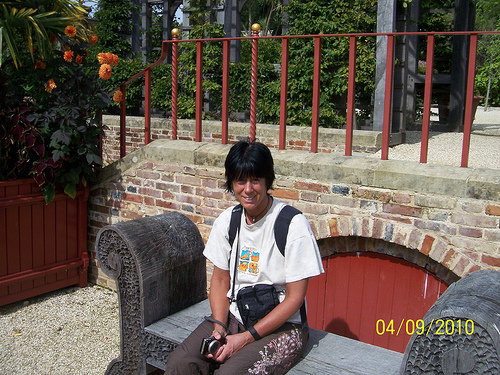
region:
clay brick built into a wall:
[417, 233, 436, 257]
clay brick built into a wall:
[407, 225, 424, 252]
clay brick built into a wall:
[392, 221, 408, 246]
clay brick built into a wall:
[374, 200, 428, 218]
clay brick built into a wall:
[288, 178, 335, 193]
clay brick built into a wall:
[169, 190, 206, 205]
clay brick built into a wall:
[123, 184, 139, 194]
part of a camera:
[200, 334, 222, 357]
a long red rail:
[105, 21, 492, 171]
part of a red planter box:
[0, 171, 100, 313]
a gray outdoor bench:
[95, 200, 498, 373]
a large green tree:
[227, 0, 374, 118]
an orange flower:
[90, 45, 120, 65]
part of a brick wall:
[85, 160, 497, 276]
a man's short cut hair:
[213, 136, 274, 197]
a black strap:
[272, 202, 295, 257]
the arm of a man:
[196, 216, 238, 340]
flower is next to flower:
[63, 23, 76, 37]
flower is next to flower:
[88, 32, 99, 43]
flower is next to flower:
[60, 48, 76, 62]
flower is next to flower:
[41, 75, 56, 94]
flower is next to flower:
[97, 64, 113, 80]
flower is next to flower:
[112, 89, 122, 101]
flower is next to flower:
[96, 55, 106, 65]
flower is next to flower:
[104, 50, 114, 61]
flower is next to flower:
[111, 53, 118, 64]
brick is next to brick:
[301, 190, 324, 203]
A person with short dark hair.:
[221, 140, 279, 211]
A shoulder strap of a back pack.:
[269, 200, 301, 260]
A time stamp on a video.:
[373, 315, 477, 337]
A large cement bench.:
[86, 202, 497, 370]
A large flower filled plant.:
[0, 0, 108, 204]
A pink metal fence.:
[101, 31, 497, 173]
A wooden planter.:
[0, 168, 96, 326]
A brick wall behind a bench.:
[87, 140, 495, 293]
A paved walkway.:
[361, 111, 498, 166]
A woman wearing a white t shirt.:
[201, 200, 321, 325]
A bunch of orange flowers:
[29, 18, 129, 106]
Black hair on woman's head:
[219, 138, 279, 212]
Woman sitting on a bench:
[91, 138, 496, 373]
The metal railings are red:
[93, 29, 498, 171]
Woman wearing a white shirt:
[200, 140, 326, 324]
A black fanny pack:
[235, 282, 283, 328]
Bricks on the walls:
[88, 125, 498, 298]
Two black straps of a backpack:
[225, 202, 303, 257]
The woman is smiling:
[220, 139, 278, 211]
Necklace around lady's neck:
[240, 194, 273, 226]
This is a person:
[185, 125, 315, 370]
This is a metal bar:
[271, 26, 293, 162]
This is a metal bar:
[302, 26, 329, 169]